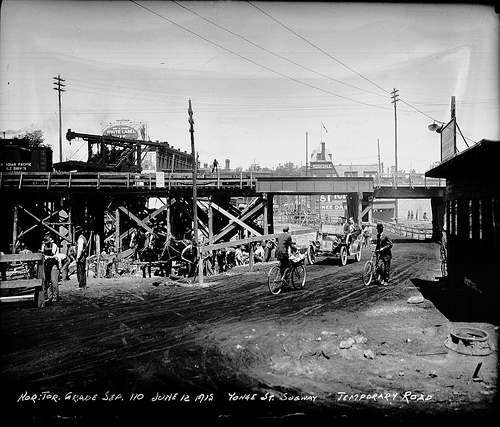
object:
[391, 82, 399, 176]
posts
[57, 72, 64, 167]
posts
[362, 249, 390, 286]
bicycle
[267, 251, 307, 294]
bicycle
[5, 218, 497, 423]
road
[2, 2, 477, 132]
lines